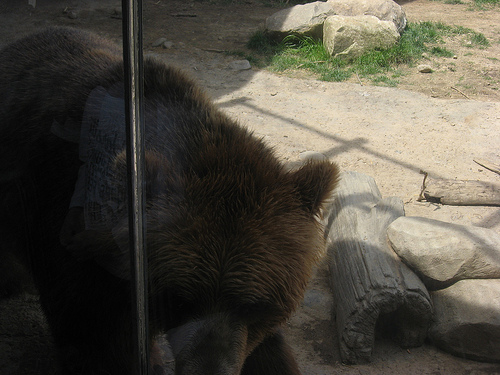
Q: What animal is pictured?
A: Grizzly bear.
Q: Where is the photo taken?
A: A zoo.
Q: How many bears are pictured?
A: One.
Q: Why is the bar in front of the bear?
A: Security.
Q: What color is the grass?
A: Green.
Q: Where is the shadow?
A: On the ground.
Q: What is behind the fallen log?
A: Rocks.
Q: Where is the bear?
A: In an enclosure.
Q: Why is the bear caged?
A: In a zoo.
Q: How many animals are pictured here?
A: One.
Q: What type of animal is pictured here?
A: Bear.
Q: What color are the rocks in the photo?
A: Grey.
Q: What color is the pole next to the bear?
A: Black.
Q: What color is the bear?
A: Brown.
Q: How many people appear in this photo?
A: Zero.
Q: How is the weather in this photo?
A: Sunny.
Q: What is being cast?
A: Shadows.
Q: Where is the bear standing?
A: In the shadows.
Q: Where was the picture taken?
A: In a zoo.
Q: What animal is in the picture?
A: A bear.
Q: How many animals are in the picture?
A: 1.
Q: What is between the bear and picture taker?
A: Glass.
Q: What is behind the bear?
A: A fake log.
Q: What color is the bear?
A: Brown.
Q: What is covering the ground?
A: Dirt.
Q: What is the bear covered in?
A: Fur.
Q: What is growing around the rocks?
A: Grass.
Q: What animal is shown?
A: Bear.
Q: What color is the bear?
A: Brown.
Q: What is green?
A: Grass.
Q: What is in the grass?
A: Rocks.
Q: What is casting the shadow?
A: A fence.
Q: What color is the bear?
A: Brown.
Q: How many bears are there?
A: One.